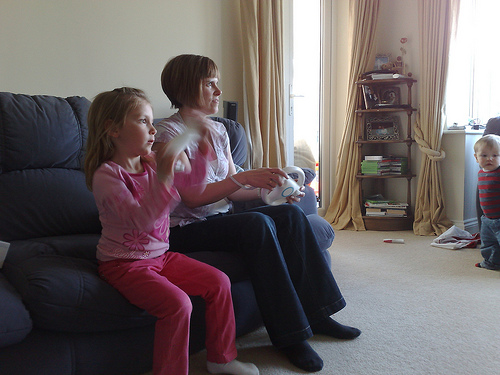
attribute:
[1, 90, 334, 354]
couch — blue, dark blue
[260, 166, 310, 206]
game controller — steering wheel, white wheel, wii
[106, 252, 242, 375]
pants — pink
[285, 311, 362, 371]
socks — black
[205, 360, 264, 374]
sock — white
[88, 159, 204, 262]
top — floral print, pink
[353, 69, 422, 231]
shelf — five, wooden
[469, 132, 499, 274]
boy — standing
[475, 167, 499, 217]
shirt — gray, red striped, striped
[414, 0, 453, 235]
curtains — open, beige, yellow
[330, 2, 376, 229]
curtains — yellow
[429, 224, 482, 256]
plastic bag — red, white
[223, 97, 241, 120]
speaker — black, gray